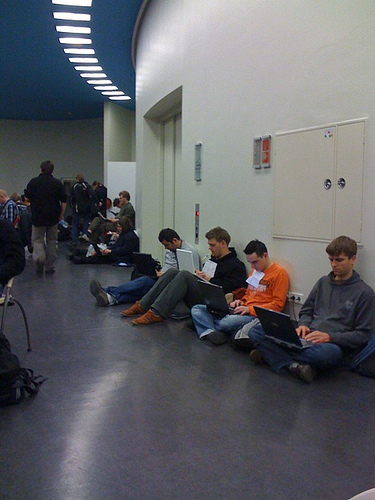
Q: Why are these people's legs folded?
A: They're sitting down.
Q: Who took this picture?
A: A photographer.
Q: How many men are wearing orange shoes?
A: One.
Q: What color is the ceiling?
A: Blue.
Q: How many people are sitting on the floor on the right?
A: Four.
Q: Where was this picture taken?
A: Inside the building.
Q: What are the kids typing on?
A: Laptops.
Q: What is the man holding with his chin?
A: A piece of paper.